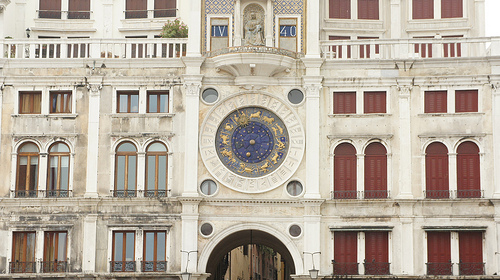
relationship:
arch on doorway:
[212, 225, 288, 256] [212, 232, 294, 279]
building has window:
[8, 7, 493, 277] [329, 139, 356, 201]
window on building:
[421, 91, 442, 113] [10, 50, 495, 250]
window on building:
[421, 91, 442, 113] [8, 7, 493, 277]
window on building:
[423, 87, 478, 115] [8, 7, 493, 277]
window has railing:
[41, 227, 70, 274] [12, 241, 70, 274]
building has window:
[8, 7, 493, 277] [420, 132, 457, 199]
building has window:
[8, 7, 493, 277] [137, 139, 172, 200]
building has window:
[8, 7, 493, 277] [140, 81, 182, 123]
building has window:
[8, 7, 493, 277] [39, 132, 88, 205]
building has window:
[8, 7, 493, 277] [141, 84, 174, 118]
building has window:
[8, 7, 493, 277] [105, 84, 143, 116]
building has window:
[0, 7, 490, 279] [112, 150, 129, 197]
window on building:
[141, 140, 170, 198] [8, 7, 493, 277]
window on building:
[327, 130, 388, 200] [8, 7, 493, 277]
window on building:
[141, 133, 172, 199] [8, 7, 493, 277]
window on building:
[459, 228, 484, 272] [8, 7, 493, 277]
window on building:
[334, 230, 358, 272] [8, 7, 493, 277]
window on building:
[144, 231, 166, 268] [8, 7, 493, 277]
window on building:
[115, 230, 132, 267] [8, 7, 493, 277]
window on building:
[41, 229, 70, 273] [8, 7, 493, 277]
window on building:
[13, 230, 36, 270] [8, 7, 493, 277]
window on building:
[149, 93, 167, 110] [8, 7, 493, 277]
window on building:
[45, 92, 73, 115] [8, 7, 493, 277]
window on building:
[18, 92, 40, 111] [8, 7, 493, 277]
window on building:
[147, 137, 168, 193] [8, 7, 493, 277]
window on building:
[113, 138, 137, 192] [8, 7, 493, 277]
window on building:
[46, 140, 71, 196] [8, 7, 493, 277]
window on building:
[17, 144, 38, 191] [8, 7, 493, 277]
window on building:
[46, 140, 71, 200] [8, 7, 493, 277]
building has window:
[8, 7, 493, 277] [143, 87, 158, 113]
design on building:
[83, 59, 114, 87] [8, 7, 493, 277]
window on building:
[157, 89, 169, 113] [8, 7, 493, 277]